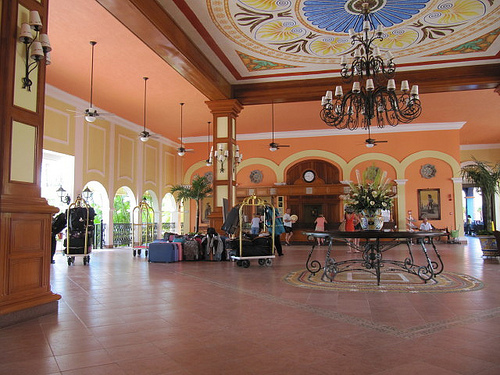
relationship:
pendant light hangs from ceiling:
[363, 137, 374, 149] [105, 0, 499, 107]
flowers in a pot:
[335, 174, 395, 215] [318, 159, 395, 237]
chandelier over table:
[324, 27, 427, 134] [303, 225, 447, 280]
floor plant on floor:
[459, 153, 499, 260] [1, 237, 496, 372]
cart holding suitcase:
[215, 192, 303, 274] [225, 203, 245, 238]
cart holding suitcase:
[215, 192, 303, 274] [262, 203, 286, 235]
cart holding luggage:
[215, 192, 303, 274] [235, 237, 273, 258]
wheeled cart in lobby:
[120, 194, 161, 256] [36, 98, 465, 354]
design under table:
[289, 257, 480, 297] [292, 224, 454, 284]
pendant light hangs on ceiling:
[138, 76, 152, 145] [43, 0, 498, 145]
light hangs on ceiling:
[167, 129, 197, 169] [196, 15, 304, 100]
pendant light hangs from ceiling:
[203, 120, 213, 168] [46, 0, 496, 125]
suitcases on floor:
[146, 232, 240, 261] [1, 237, 496, 372]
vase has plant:
[359, 205, 384, 230] [343, 162, 398, 217]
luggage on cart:
[235, 237, 273, 258] [233, 191, 275, 263]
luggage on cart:
[148, 242, 179, 263] [233, 191, 275, 263]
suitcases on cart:
[200, 232, 223, 260] [233, 191, 275, 263]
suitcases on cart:
[69, 207, 90, 224] [63, 195, 95, 262]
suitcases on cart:
[63, 233, 91, 255] [63, 195, 95, 262]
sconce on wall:
[20, 8, 57, 100] [5, 16, 55, 293]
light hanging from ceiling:
[64, 45, 111, 125] [115, 7, 331, 89]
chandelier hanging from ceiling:
[319, 10, 423, 130] [260, 80, 293, 91]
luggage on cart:
[247, 236, 271, 251] [224, 182, 297, 285]